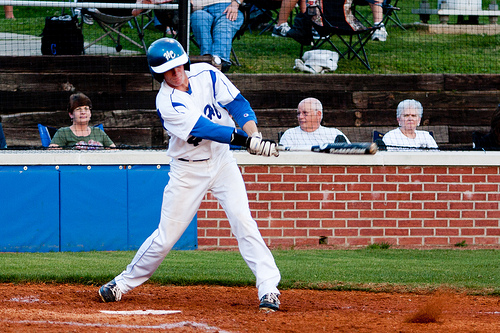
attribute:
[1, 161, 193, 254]
padded — blue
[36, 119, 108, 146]
chair — blue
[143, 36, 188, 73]
helmet — baseball, blue, hard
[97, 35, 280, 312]
player — baseball, young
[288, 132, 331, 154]
shirt — green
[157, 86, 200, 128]
shirt — green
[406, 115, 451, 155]
wall — brick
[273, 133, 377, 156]
bat — blue, white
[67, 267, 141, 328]
cleats — baseball, blue and white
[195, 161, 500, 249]
brick wall — red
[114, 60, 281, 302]
baseball uniform — blue, white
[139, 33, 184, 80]
helmet — metallic, blue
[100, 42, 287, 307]
man — white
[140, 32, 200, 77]
helmet — white, blue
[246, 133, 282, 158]
gloves — white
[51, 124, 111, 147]
shirt — short-sleeve, green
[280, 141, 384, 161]
bat — dark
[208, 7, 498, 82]
fencing — black, metal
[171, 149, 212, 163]
belt — dark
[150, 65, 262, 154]
jersey — blue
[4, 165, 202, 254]
wall — padded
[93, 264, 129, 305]
foot — tilted